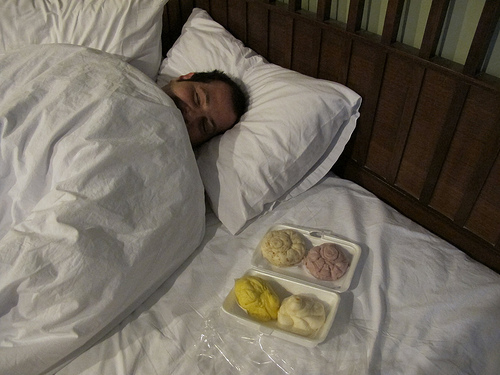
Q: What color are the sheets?
A: White.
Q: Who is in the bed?
A: The man.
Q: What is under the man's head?
A: A pillow.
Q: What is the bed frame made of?
A: Wood.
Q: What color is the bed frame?
A: Brown.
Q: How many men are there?
A: One.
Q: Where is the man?
A: In the bed.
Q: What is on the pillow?
A: The man's head.